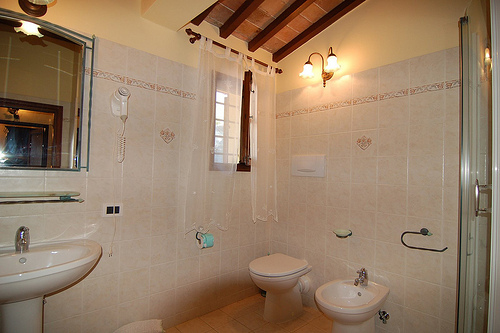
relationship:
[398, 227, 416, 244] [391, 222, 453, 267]
metal towel holder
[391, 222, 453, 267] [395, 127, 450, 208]
holder on wall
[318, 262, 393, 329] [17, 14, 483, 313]
bidet in bathroom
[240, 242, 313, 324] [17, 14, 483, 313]
toilet in bathroom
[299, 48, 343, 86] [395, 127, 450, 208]
fixture on wall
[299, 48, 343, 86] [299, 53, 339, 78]
fixture has bulbs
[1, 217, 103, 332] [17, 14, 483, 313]
sink in bathroom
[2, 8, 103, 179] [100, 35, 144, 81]
mirror on wall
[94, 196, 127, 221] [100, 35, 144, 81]
outlet on wall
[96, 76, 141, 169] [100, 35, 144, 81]
dryer on wall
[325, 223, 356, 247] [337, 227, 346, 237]
holder for soap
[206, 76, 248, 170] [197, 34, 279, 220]
window with curtains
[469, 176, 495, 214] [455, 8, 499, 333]
handle of shower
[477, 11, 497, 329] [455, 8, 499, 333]
door of shower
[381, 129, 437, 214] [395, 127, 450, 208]
tile on wall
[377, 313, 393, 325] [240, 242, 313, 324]
valve of toilet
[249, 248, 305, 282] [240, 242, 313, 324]
seat of toilet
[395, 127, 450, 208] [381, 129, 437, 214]
wall of tile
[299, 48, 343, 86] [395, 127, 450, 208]
lights on wall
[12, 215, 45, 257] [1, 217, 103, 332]
faucet of sink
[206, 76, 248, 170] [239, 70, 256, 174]
window of wood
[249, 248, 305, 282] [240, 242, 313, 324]
lid of toilet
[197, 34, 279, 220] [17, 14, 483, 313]
curtain of bathroom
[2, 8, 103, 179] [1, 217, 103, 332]
mirror over sink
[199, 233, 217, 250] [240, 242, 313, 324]
paper beside toilet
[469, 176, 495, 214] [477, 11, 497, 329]
handle of door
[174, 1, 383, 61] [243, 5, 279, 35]
roof of wood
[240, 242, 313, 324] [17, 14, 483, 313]
toilet of bathroom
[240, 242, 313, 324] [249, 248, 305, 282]
toilet with lid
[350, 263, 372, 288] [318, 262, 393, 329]
faucet of bidet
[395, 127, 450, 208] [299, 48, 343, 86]
wall with fixture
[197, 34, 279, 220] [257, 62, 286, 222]
curtains of lace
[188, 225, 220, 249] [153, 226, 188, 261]
dispenser on wall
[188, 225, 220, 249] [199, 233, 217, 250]
dispenser for paper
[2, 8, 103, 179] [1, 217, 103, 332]
mirror above sink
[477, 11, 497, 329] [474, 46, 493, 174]
door of glass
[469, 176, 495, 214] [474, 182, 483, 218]
handle of silver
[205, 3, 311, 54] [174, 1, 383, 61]
beams on ceiling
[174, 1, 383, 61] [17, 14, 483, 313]
ceiling of bathroom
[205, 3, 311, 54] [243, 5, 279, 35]
beams of wood